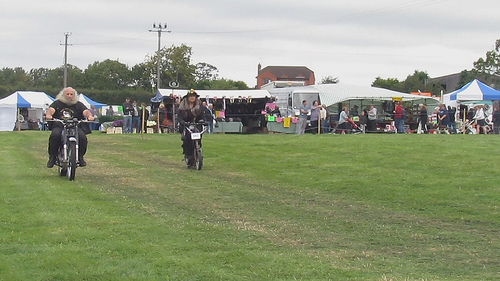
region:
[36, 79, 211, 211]
two people on bikes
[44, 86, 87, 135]
man has black shirt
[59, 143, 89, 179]
bikes have black wheels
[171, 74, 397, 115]
white tents behind men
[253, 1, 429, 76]
sky is grey and cloudy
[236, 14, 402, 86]
layered clouds in sky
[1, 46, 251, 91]
green trees behind men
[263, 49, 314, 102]
large brown and orange house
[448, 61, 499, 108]
blue and white tent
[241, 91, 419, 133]
people are watching race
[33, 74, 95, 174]
this is a motorist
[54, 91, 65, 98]
the man is hairy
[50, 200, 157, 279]
the grass is short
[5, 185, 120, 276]
the grass are short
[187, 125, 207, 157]
this is a bike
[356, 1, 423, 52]
this is the sky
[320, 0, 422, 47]
the sky is white in color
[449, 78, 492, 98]
this is a tent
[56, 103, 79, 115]
the t shirt is black in color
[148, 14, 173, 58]
this is the pole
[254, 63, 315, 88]
large red brick building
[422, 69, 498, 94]
square gray building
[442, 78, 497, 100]
blue and white umbrella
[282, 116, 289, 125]
yellow fabric on the table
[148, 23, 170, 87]
tall power pole with three things on top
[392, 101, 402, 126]
person in red shirt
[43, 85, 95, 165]
man on a motorcycle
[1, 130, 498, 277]
short green grass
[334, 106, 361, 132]
person on a red scooter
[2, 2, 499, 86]
part of overcast sky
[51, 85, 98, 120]
Person has long gray beard.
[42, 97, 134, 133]
Person wearing black shirt.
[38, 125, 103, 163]
Person wearing black pants.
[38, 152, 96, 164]
Person wearing black shoes.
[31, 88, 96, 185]
Person riding bike on grass.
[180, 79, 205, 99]
Person wearing hat on head.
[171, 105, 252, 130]
Person wearing black jacket.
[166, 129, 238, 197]
Person riding bike in grass.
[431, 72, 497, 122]
Blue and white tent behind people.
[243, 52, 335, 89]
Large building in distance.